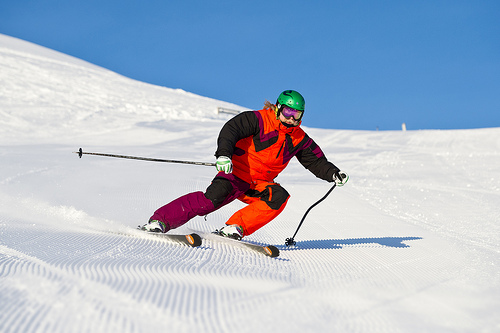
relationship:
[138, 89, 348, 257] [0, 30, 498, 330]
man skiing down slope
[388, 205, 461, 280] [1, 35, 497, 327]
snow covering ski slope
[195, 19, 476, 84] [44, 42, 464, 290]
sky in photo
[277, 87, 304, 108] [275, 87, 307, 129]
helmet on head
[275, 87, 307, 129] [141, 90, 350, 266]
head of skier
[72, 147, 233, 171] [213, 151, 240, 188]
pole in hand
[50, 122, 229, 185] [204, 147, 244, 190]
pole in hand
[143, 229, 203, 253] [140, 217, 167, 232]
ski on foot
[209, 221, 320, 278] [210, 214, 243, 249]
ski on foot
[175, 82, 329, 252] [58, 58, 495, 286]
upper torso of skier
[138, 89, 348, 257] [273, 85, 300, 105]
man wears helmet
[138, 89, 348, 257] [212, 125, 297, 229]
man wears suit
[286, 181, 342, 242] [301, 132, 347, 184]
pole on hand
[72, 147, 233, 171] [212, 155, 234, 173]
pole on right hand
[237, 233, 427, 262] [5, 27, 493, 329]
shadow on snow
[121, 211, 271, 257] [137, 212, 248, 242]
pair of shoes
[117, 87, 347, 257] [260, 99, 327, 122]
man wearing goggles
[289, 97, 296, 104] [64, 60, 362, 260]
green on skier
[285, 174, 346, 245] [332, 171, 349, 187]
pole in hand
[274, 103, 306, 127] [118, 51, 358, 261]
goggles on skier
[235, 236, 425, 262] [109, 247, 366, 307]
shadow on ground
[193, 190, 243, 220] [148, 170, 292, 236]
zipper on front of pants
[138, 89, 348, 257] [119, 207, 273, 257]
man wearing skis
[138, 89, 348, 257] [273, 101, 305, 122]
man wearing goggles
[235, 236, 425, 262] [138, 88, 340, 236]
shadow of skier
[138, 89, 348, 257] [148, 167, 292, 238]
man wearing pants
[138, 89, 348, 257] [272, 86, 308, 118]
man wearing helmet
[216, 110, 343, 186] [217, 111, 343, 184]
ski jacket with sleeves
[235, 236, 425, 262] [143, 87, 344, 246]
shadow of skier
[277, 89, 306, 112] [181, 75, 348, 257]
helmet on person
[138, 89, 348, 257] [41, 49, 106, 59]
man on hill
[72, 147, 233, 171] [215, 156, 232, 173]
pole in hand